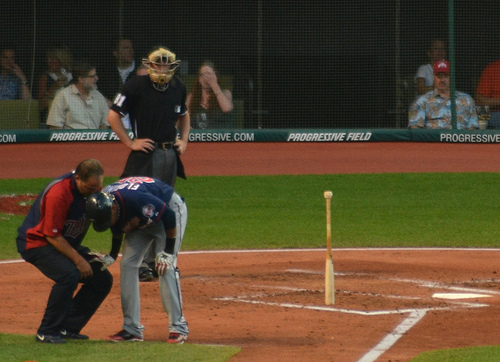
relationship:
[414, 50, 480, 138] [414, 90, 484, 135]
fan wearing shirt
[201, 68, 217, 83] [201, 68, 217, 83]
hand over hand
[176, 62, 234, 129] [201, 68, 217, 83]
lady with hand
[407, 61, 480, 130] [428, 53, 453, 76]
fan wears red cap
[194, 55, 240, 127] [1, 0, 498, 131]
lady behind net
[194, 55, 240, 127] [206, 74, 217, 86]
lady has hand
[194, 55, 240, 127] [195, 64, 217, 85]
lady has face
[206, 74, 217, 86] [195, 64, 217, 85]
hand over face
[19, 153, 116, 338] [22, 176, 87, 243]
man wears shirt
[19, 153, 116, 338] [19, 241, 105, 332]
man wears pants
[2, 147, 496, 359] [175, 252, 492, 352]
field has dirt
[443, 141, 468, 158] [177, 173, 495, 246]
ground has grass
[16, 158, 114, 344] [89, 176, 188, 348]
man whispering to baseball player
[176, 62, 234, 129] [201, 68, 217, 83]
lady covering hand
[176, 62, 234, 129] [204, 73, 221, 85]
lady has hand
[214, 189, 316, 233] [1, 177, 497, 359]
grass on field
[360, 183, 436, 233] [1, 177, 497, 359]
grass on field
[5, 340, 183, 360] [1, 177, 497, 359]
grass on field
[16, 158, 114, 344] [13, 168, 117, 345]
man wears uniform